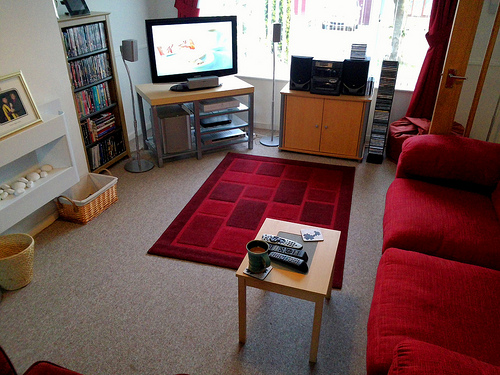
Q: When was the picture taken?
A: Daytime.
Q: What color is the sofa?
A: Red.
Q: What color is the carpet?
A: Gray.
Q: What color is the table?
A: Brown.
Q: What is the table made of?
A: Wood.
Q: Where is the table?
A: In front of the sofa.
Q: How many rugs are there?
A: One.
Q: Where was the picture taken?
A: In a living room.